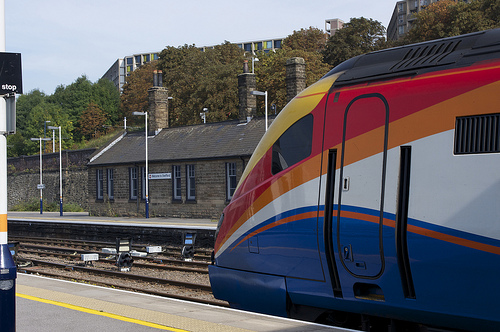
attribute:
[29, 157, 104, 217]
wall — brown, stone, in background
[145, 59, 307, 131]
chimneys — tiled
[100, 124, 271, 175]
roof — brown, tiled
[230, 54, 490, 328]
train — colorful, stop sign, modern, blue, white, orange, red, yellow, stripes, side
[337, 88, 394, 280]
door — closed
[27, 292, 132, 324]
line — yellow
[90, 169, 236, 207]
wall — tiled